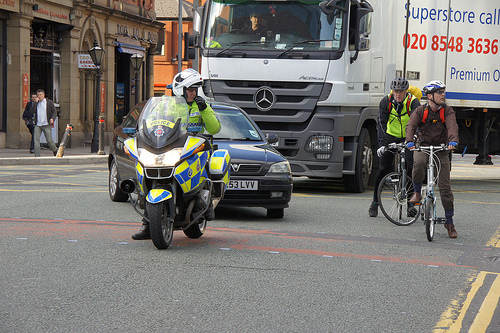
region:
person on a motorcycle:
[119, 68, 232, 250]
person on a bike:
[390, 81, 472, 247]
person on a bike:
[358, 69, 433, 221]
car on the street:
[101, 82, 305, 227]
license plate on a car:
[212, 171, 267, 194]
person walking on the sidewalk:
[26, 87, 63, 158]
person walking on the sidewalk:
[17, 88, 42, 157]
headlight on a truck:
[302, 128, 339, 162]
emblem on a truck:
[250, 85, 280, 115]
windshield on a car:
[202, 104, 275, 144]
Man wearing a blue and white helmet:
[425, 81, 448, 108]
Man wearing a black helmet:
[384, 75, 413, 100]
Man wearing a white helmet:
[169, 65, 203, 100]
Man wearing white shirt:
[30, 96, 53, 131]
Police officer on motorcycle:
[128, 72, 228, 230]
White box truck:
[211, 4, 373, 133]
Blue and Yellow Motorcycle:
[152, 137, 223, 234]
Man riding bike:
[417, 96, 440, 242]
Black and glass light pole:
[93, 42, 103, 161]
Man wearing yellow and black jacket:
[378, 96, 410, 143]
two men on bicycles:
[366, 67, 466, 252]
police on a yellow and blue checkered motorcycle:
[125, 63, 235, 261]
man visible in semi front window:
[211, 1, 368, 178]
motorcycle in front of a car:
[94, 70, 299, 268]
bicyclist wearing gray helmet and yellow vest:
[360, 71, 425, 231]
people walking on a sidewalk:
[23, 85, 73, 170]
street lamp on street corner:
[76, 39, 110, 176]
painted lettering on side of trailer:
[393, 3, 498, 88]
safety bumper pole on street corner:
[53, 120, 84, 168]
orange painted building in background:
[145, 3, 205, 99]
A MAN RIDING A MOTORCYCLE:
[122, 60, 245, 251]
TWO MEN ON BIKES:
[359, 58, 466, 258]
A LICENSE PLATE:
[216, 172, 266, 195]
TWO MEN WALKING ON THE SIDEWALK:
[18, 86, 64, 156]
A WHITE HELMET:
[164, 66, 216, 101]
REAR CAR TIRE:
[100, 155, 126, 205]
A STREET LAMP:
[85, 40, 108, 158]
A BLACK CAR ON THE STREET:
[95, 90, 300, 223]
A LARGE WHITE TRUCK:
[165, 5, 495, 197]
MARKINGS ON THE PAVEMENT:
[420, 258, 495, 328]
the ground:
[221, 241, 325, 323]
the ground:
[259, 227, 359, 307]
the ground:
[295, 240, 325, 292]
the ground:
[289, 253, 347, 329]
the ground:
[297, 174, 370, 329]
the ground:
[319, 225, 372, 319]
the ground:
[284, 104, 357, 313]